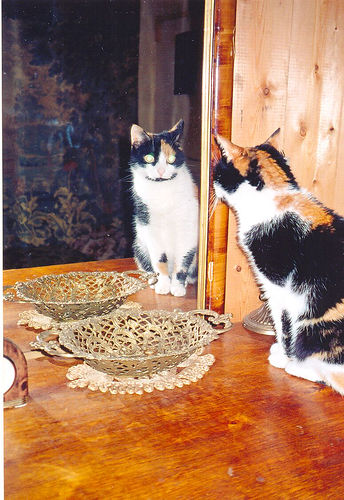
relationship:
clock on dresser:
[0, 309, 46, 422] [3, 299, 343, 498]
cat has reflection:
[205, 120, 337, 369] [77, 82, 232, 294]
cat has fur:
[205, 120, 337, 369] [238, 129, 343, 386]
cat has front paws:
[205, 120, 337, 369] [142, 253, 204, 309]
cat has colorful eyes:
[205, 120, 337, 369] [135, 144, 180, 168]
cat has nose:
[205, 120, 337, 369] [150, 165, 169, 175]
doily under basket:
[58, 341, 221, 392] [45, 279, 214, 401]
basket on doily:
[45, 279, 214, 401] [58, 341, 221, 392]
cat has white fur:
[205, 120, 337, 369] [208, 172, 309, 367]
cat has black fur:
[205, 120, 337, 369] [251, 208, 341, 318]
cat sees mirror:
[205, 120, 337, 369] [9, 5, 188, 328]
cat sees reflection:
[205, 120, 337, 369] [77, 82, 232, 294]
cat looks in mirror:
[205, 120, 337, 369] [9, 5, 188, 328]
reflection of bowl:
[77, 82, 232, 294] [41, 303, 219, 373]